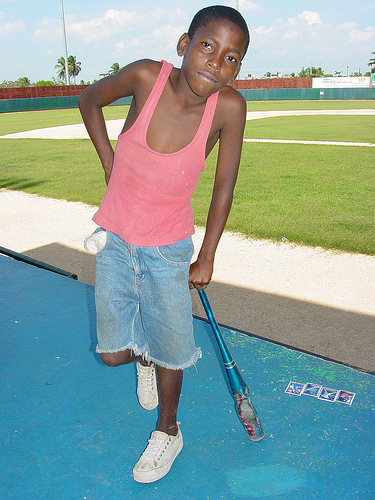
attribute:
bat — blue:
[186, 274, 274, 450]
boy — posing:
[75, 3, 251, 484]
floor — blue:
[7, 252, 357, 481]